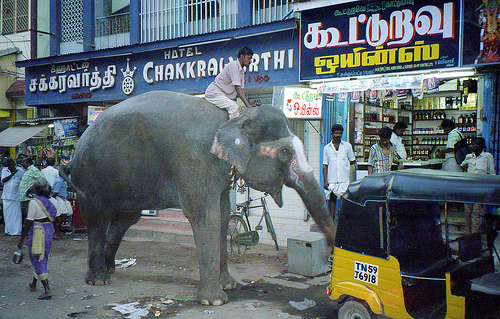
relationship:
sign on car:
[349, 259, 381, 285] [325, 167, 499, 318]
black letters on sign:
[355, 262, 377, 283] [352, 258, 380, 286]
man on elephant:
[204, 44, 254, 121] [60, 88, 327, 308]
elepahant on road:
[64, 89, 344, 303] [0, 228, 340, 317]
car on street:
[325, 164, 499, 317] [0, 228, 352, 317]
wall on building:
[0, 1, 499, 248] [3, 9, 496, 317]